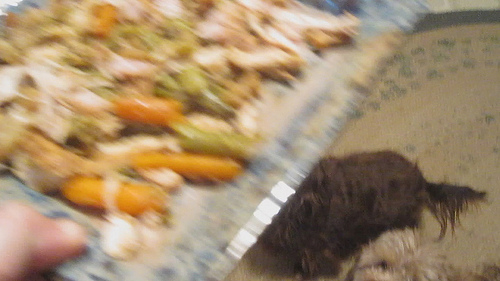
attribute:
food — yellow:
[60, 161, 179, 223]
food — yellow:
[120, 140, 250, 191]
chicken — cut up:
[0, 0, 352, 214]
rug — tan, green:
[327, 5, 499, 279]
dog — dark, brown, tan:
[259, 149, 488, 278]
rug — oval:
[227, 26, 497, 280]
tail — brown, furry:
[424, 178, 489, 213]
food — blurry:
[4, 5, 307, 203]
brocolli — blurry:
[159, 69, 238, 116]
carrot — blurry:
[88, 2, 118, 38]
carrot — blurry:
[111, 90, 191, 123]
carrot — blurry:
[130, 149, 240, 179]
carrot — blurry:
[68, 175, 158, 211]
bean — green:
[174, 125, 254, 163]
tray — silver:
[0, 3, 431, 280]